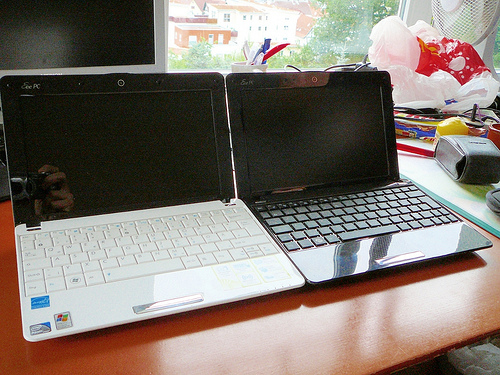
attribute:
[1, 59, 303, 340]
laptop — white, black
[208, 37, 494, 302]
laptop — black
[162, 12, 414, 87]
window — large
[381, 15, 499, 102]
bag — white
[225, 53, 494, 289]
laptop — black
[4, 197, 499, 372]
table — brown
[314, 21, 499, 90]
bag — white, plastic, red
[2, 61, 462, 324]
laptop — blue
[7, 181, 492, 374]
desk — wood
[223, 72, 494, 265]
laptop — white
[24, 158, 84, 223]
hand — reflected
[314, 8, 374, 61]
plants — large 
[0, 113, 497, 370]
desk — wooden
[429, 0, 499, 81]
fan — white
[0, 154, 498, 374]
table — brown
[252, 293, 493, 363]
table — brown